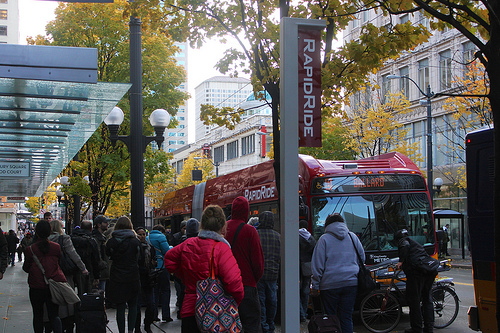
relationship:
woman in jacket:
[159, 200, 250, 331] [163, 236, 245, 315]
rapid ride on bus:
[241, 185, 279, 199] [138, 110, 447, 324]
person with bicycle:
[387, 225, 447, 325] [357, 269, 459, 333]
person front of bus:
[387, 225, 447, 325] [138, 110, 447, 324]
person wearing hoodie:
[214, 195, 272, 328] [217, 190, 269, 289]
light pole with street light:
[128, 8, 145, 245] [146, 107, 177, 147]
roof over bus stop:
[3, 42, 137, 201] [6, 2, 339, 326]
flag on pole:
[295, 23, 323, 149] [277, 12, 327, 328]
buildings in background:
[150, 44, 492, 265] [72, 1, 500, 292]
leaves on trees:
[31, 0, 492, 212] [21, 2, 499, 276]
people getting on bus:
[25, 197, 441, 328] [138, 110, 447, 324]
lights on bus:
[317, 165, 425, 181] [138, 110, 447, 324]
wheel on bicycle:
[360, 285, 403, 327] [357, 257, 468, 327]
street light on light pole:
[105, 104, 129, 152] [127, 8, 147, 245]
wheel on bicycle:
[415, 282, 460, 330] [357, 257, 468, 327]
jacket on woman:
[163, 236, 245, 315] [159, 200, 250, 331]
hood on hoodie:
[230, 196, 249, 221] [217, 196, 266, 289]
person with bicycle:
[387, 228, 447, 333] [357, 257, 468, 327]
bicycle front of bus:
[357, 257, 468, 327] [138, 110, 447, 324]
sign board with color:
[294, 27, 325, 147] [300, 33, 318, 143]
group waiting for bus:
[16, 190, 444, 324] [138, 110, 447, 324]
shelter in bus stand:
[3, 42, 137, 201] [6, 2, 339, 326]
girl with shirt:
[20, 217, 78, 326] [19, 241, 64, 289]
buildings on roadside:
[150, 44, 492, 265] [361, 251, 475, 321]